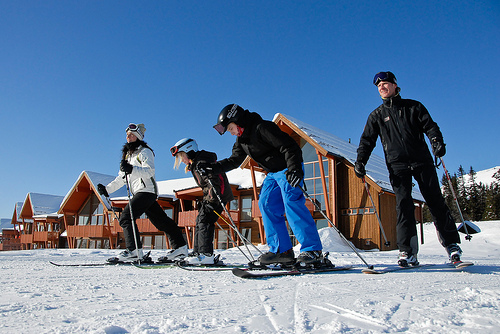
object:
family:
[49, 71, 475, 279]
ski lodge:
[17, 112, 425, 250]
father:
[352, 71, 462, 266]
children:
[169, 138, 234, 268]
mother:
[213, 102, 335, 268]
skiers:
[48, 102, 354, 277]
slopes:
[1, 281, 85, 324]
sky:
[156, 14, 214, 31]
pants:
[258, 160, 324, 255]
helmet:
[212, 104, 244, 136]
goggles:
[373, 72, 396, 86]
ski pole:
[198, 179, 265, 265]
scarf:
[119, 139, 156, 173]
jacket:
[106, 145, 159, 201]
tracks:
[109, 292, 193, 331]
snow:
[336, 285, 407, 304]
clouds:
[454, 109, 463, 150]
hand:
[354, 162, 366, 179]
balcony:
[66, 213, 116, 237]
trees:
[420, 165, 500, 224]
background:
[424, 161, 500, 218]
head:
[372, 71, 398, 99]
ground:
[348, 292, 408, 316]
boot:
[292, 249, 330, 271]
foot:
[397, 250, 419, 267]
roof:
[155, 176, 210, 200]